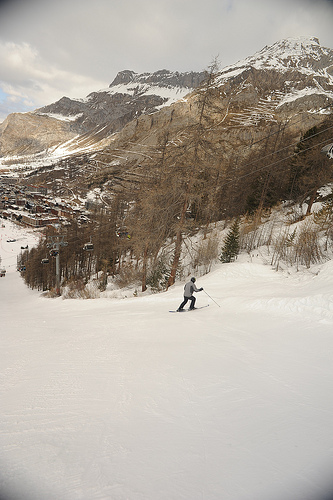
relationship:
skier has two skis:
[170, 276, 204, 311] [170, 302, 211, 314]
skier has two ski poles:
[177, 277, 204, 311] [202, 286, 224, 311]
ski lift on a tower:
[115, 222, 130, 240] [53, 240, 63, 299]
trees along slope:
[70, 115, 332, 279] [2, 314, 332, 498]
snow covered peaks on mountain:
[245, 34, 333, 72] [148, 35, 331, 178]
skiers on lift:
[50, 248, 61, 259] [183, 200, 197, 224]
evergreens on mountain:
[70, 115, 332, 279] [148, 35, 331, 178]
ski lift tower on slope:
[46, 238, 70, 296] [2, 314, 332, 498]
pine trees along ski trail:
[70, 115, 332, 279] [0, 298, 182, 439]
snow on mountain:
[245, 34, 333, 72] [148, 35, 331, 178]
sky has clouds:
[0, 0, 112, 85] [0, 42, 88, 101]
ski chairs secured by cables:
[114, 216, 135, 241] [216, 137, 331, 185]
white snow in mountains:
[2, 314, 332, 498] [195, 35, 332, 232]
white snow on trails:
[2, 314, 332, 498] [0, 235, 30, 426]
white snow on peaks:
[2, 314, 332, 498] [245, 34, 333, 72]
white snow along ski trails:
[2, 314, 332, 498] [51, 132, 96, 163]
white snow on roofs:
[2, 314, 332, 498] [13, 207, 25, 217]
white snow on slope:
[2, 314, 332, 498] [2, 291, 332, 499]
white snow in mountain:
[2, 314, 332, 498] [148, 35, 331, 178]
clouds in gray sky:
[0, 42, 88, 101] [0, 1, 238, 61]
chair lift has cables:
[46, 238, 70, 296] [216, 137, 331, 185]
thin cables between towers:
[213, 127, 332, 193] [46, 238, 70, 296]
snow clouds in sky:
[0, 42, 88, 101] [0, 1, 238, 61]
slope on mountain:
[2, 291, 332, 499] [148, 35, 331, 178]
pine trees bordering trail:
[70, 115, 332, 279] [0, 299, 174, 499]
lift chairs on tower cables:
[81, 239, 97, 256] [216, 137, 331, 185]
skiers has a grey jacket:
[170, 276, 204, 311] [183, 280, 201, 298]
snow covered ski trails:
[2, 314, 332, 498] [51, 132, 96, 163]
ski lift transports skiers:
[46, 238, 70, 296] [170, 276, 204, 311]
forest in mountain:
[70, 115, 332, 279] [148, 35, 331, 178]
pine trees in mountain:
[70, 115, 332, 279] [148, 35, 331, 178]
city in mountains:
[1, 180, 54, 231] [195, 35, 332, 232]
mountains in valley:
[195, 35, 332, 232] [0, 37, 332, 280]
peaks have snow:
[237, 33, 332, 95] [245, 34, 333, 72]